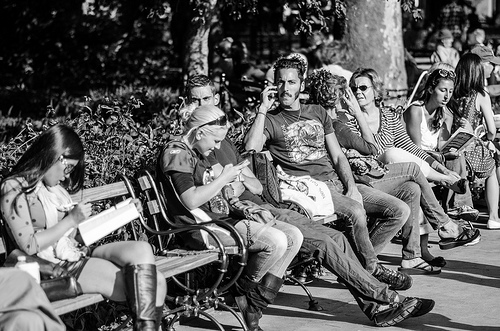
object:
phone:
[268, 81, 277, 101]